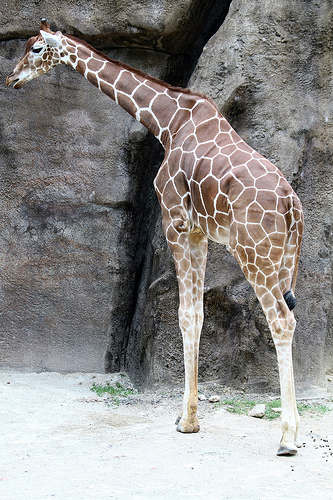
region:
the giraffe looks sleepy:
[0, 7, 83, 105]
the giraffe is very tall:
[4, 0, 320, 456]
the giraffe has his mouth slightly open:
[3, 12, 72, 114]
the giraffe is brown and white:
[75, 10, 302, 476]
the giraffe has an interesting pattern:
[24, 19, 330, 214]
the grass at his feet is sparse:
[93, 381, 138, 402]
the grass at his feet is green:
[87, 371, 128, 414]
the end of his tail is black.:
[283, 249, 316, 336]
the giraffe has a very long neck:
[17, 18, 224, 152]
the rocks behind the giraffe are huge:
[210, 15, 309, 116]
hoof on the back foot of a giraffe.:
[274, 434, 300, 463]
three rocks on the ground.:
[198, 387, 271, 425]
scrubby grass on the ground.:
[90, 370, 125, 409]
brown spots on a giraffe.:
[238, 221, 263, 252]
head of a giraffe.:
[5, 15, 71, 95]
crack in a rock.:
[92, 258, 154, 362]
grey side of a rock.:
[18, 247, 119, 359]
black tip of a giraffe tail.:
[279, 290, 299, 312]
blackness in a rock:
[186, 27, 199, 55]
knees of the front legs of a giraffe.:
[174, 301, 213, 335]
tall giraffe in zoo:
[2, 17, 315, 448]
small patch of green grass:
[90, 381, 141, 401]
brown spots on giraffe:
[180, 134, 246, 202]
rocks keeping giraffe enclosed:
[26, 120, 160, 367]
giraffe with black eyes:
[25, 37, 52, 66]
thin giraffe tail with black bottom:
[267, 193, 313, 314]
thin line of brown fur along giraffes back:
[43, 27, 225, 97]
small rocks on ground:
[197, 378, 275, 422]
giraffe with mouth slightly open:
[6, 13, 83, 97]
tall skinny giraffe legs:
[160, 185, 218, 433]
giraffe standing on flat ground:
[5, 18, 311, 461]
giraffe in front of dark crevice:
[114, 5, 223, 279]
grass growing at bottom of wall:
[65, 364, 322, 424]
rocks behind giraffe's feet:
[193, 377, 274, 433]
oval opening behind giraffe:
[217, 75, 253, 130]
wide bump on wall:
[15, 173, 89, 228]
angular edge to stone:
[92, 218, 138, 374]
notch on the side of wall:
[85, 189, 136, 227]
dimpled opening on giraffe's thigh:
[172, 199, 186, 237]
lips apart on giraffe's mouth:
[1, 65, 33, 99]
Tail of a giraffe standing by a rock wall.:
[281, 204, 297, 313]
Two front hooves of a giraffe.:
[175, 413, 201, 434]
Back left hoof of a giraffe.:
[275, 439, 299, 458]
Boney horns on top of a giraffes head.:
[36, 16, 50, 32]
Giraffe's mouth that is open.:
[6, 76, 23, 86]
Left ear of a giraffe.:
[39, 29, 56, 46]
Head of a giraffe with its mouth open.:
[6, 18, 71, 90]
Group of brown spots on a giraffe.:
[218, 154, 253, 205]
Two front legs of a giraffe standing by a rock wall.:
[160, 220, 207, 433]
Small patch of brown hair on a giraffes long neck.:
[174, 86, 195, 95]